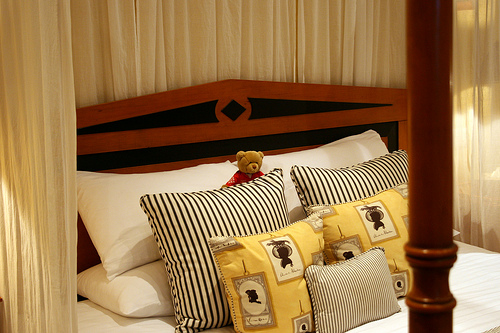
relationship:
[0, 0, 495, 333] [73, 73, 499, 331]
curtain surrounds bed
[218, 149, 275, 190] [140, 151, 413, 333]
teddy bear behind pillow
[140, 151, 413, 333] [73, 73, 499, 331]
pillow on top of bed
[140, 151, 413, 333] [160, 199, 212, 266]
pillow has stripes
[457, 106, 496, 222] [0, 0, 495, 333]
light visible behind curtain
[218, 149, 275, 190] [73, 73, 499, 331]
teddy bear on top of bed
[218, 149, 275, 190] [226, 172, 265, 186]
teddy bear wearing shirt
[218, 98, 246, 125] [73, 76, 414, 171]
square in middle of headboard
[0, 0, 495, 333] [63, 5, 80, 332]
curtain has edge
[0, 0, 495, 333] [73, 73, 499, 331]
curtains are surrounding bed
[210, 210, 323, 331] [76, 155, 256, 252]
pillow next to pillow